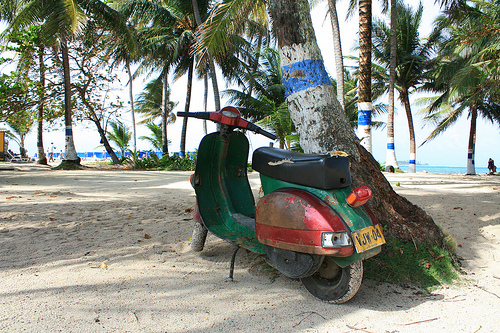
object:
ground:
[391, 168, 459, 222]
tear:
[325, 150, 349, 159]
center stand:
[227, 246, 241, 282]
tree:
[82, 24, 144, 164]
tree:
[37, 19, 86, 171]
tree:
[0, 24, 56, 166]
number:
[372, 228, 383, 241]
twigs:
[293, 253, 500, 333]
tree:
[187, 0, 466, 288]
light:
[346, 185, 373, 207]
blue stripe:
[281, 59, 333, 98]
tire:
[299, 256, 363, 304]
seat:
[251, 145, 352, 189]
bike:
[175, 106, 386, 305]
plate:
[350, 227, 372, 249]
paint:
[280, 57, 328, 94]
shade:
[195, 294, 358, 333]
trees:
[340, 0, 500, 178]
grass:
[363, 224, 473, 291]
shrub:
[120, 148, 198, 171]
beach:
[0, 150, 500, 332]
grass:
[97, 150, 254, 172]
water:
[398, 164, 499, 174]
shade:
[0, 166, 217, 269]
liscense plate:
[350, 223, 386, 253]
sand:
[1, 172, 500, 333]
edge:
[288, 271, 305, 279]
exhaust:
[318, 257, 352, 284]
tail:
[345, 185, 373, 207]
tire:
[190, 221, 208, 252]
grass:
[380, 165, 406, 174]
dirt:
[345, 264, 364, 298]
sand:
[53, 200, 148, 300]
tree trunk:
[290, 97, 462, 284]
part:
[82, 205, 120, 241]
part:
[136, 159, 156, 161]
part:
[341, 285, 351, 288]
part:
[72, 233, 95, 246]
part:
[258, 313, 285, 328]